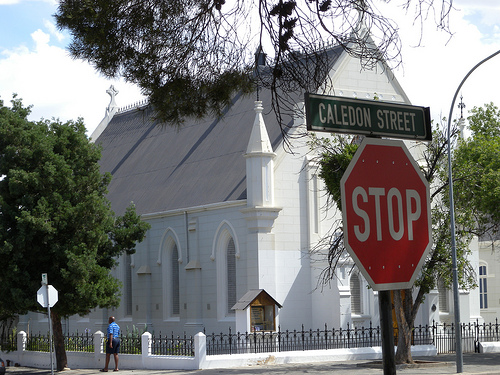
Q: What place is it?
A: It is a church.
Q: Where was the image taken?
A: It was taken at the church.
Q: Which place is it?
A: It is a church.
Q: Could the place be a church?
A: Yes, it is a church.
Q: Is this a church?
A: Yes, it is a church.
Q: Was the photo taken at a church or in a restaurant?
A: It was taken at a church.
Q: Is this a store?
A: No, it is a church.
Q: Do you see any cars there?
A: No, there are no cars.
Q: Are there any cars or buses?
A: No, there are no cars or buses.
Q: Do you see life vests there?
A: No, there are no life vests.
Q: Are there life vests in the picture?
A: No, there are no life vests.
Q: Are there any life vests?
A: No, there are no life vests.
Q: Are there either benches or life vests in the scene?
A: No, there are no life vests or benches.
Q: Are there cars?
A: No, there are no cars.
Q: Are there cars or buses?
A: No, there are no cars or buses.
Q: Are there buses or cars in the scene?
A: No, there are no cars or buses.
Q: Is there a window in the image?
A: Yes, there is a window.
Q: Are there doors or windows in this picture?
A: Yes, there is a window.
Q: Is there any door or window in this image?
A: Yes, there is a window.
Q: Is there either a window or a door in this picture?
A: Yes, there is a window.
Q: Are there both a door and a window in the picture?
A: No, there is a window but no doors.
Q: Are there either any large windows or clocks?
A: Yes, there is a large window.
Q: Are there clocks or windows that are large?
A: Yes, the window is large.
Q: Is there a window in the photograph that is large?
A: Yes, there is a large window.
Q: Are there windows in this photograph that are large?
A: Yes, there is a window that is large.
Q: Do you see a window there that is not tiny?
A: Yes, there is a large window.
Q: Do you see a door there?
A: No, there are no doors.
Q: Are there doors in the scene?
A: No, there are no doors.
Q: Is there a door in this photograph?
A: No, there are no doors.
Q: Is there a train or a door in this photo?
A: No, there are no doors or trains.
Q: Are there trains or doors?
A: No, there are no doors or trains.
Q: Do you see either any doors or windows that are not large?
A: No, there is a window but it is large.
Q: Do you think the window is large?
A: Yes, the window is large.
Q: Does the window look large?
A: Yes, the window is large.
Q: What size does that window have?
A: The window has large size.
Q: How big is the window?
A: The window is large.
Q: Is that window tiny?
A: No, the window is large.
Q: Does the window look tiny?
A: No, the window is large.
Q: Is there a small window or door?
A: No, there is a window but it is large.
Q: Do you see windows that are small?
A: No, there is a window but it is large.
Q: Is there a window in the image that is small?
A: No, there is a window but it is large.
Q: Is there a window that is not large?
A: No, there is a window but it is large.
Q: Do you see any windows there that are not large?
A: No, there is a window but it is large.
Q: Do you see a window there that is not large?
A: No, there is a window but it is large.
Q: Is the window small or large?
A: The window is large.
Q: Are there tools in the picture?
A: No, there are no tools.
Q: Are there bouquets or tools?
A: No, there are no tools or bouquets.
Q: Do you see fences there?
A: Yes, there is a fence.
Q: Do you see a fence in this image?
A: Yes, there is a fence.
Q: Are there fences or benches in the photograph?
A: Yes, there is a fence.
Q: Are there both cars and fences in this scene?
A: No, there is a fence but no cars.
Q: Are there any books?
A: No, there are no books.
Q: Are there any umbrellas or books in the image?
A: No, there are no books or umbrellas.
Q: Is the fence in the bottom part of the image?
A: Yes, the fence is in the bottom of the image.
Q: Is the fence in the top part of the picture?
A: No, the fence is in the bottom of the image.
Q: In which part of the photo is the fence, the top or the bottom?
A: The fence is in the bottom of the image.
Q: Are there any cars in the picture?
A: No, there are no cars.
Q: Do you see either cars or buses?
A: No, there are no cars or buses.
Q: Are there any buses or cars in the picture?
A: No, there are no cars or buses.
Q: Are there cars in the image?
A: No, there are no cars.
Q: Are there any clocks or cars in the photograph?
A: No, there are no cars or clocks.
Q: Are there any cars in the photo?
A: No, there are no cars.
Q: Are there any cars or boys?
A: No, there are no cars or boys.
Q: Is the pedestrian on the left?
A: Yes, the pedestrian is on the left of the image.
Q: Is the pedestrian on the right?
A: No, the pedestrian is on the left of the image.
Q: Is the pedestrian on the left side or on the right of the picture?
A: The pedestrian is on the left of the image.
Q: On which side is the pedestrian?
A: The pedestrian is on the left of the image.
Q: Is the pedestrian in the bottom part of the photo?
A: Yes, the pedestrian is in the bottom of the image.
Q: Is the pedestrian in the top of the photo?
A: No, the pedestrian is in the bottom of the image.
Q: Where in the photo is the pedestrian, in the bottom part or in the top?
A: The pedestrian is in the bottom of the image.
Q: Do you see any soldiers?
A: No, there are no soldiers.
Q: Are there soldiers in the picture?
A: No, there are no soldiers.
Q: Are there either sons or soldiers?
A: No, there are no soldiers or sons.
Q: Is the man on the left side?
A: Yes, the man is on the left of the image.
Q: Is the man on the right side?
A: No, the man is on the left of the image.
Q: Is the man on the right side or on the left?
A: The man is on the left of the image.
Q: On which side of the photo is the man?
A: The man is on the left of the image.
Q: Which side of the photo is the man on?
A: The man is on the left of the image.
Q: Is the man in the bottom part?
A: Yes, the man is in the bottom of the image.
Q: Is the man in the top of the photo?
A: No, the man is in the bottom of the image.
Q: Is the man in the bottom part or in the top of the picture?
A: The man is in the bottom of the image.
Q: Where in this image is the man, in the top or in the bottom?
A: The man is in the bottom of the image.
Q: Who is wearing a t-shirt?
A: The man is wearing a t-shirt.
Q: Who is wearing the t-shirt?
A: The man is wearing a t-shirt.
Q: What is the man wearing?
A: The man is wearing a tshirt.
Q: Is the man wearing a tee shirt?
A: Yes, the man is wearing a tee shirt.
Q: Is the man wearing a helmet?
A: No, the man is wearing a tee shirt.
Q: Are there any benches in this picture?
A: No, there are no benches.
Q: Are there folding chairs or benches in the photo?
A: No, there are no benches or folding chairs.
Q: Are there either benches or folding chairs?
A: No, there are no benches or folding chairs.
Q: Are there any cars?
A: No, there are no cars.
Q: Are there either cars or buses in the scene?
A: No, there are no cars or buses.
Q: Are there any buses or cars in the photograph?
A: No, there are no cars or buses.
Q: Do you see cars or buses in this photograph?
A: No, there are no cars or buses.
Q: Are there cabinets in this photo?
A: No, there are no cabinets.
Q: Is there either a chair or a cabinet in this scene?
A: No, there are no cabinets or chairs.